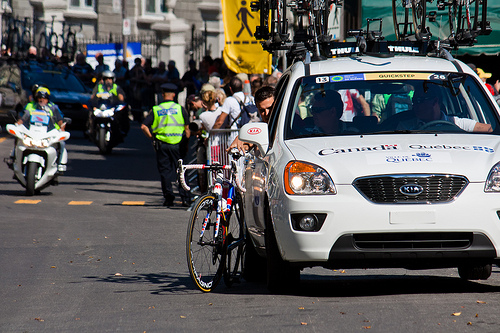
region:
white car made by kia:
[222, 50, 499, 287]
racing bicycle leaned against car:
[161, 147, 269, 298]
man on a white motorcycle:
[2, 83, 75, 208]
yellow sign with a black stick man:
[216, 0, 284, 93]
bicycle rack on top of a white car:
[245, 2, 499, 72]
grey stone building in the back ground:
[2, 0, 238, 70]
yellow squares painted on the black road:
[7, 191, 150, 219]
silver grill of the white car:
[350, 159, 475, 212]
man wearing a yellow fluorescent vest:
[136, 74, 199, 214]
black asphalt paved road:
[4, 139, 498, 331]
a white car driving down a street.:
[226, 55, 498, 292]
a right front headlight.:
[277, 153, 346, 232]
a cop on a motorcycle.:
[3, 81, 100, 218]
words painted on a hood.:
[316, 142, 496, 172]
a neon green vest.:
[141, 79, 198, 196]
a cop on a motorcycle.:
[76, 60, 132, 170]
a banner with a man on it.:
[204, 1, 288, 96]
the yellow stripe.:
[114, 191, 150, 217]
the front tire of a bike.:
[142, 177, 246, 312]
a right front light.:
[277, 208, 339, 258]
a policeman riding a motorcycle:
[2, 79, 81, 201]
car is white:
[219, 37, 498, 292]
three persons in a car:
[248, 83, 496, 135]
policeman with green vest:
[137, 79, 199, 209]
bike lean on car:
[161, 150, 253, 298]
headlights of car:
[281, 159, 498, 197]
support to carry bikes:
[251, 3, 496, 62]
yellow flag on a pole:
[214, 0, 280, 76]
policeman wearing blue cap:
[136, 74, 200, 207]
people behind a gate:
[188, 68, 257, 133]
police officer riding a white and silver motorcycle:
[3, 85, 70, 194]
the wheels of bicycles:
[245, 0, 493, 45]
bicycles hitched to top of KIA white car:
[248, 0, 497, 65]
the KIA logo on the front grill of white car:
[397, 181, 423, 195]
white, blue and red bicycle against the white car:
[174, 156, 244, 293]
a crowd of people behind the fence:
[184, 66, 254, 155]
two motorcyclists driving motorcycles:
[3, 69, 127, 196]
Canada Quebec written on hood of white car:
[318, 143, 470, 157]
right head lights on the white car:
[281, 159, 336, 195]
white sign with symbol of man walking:
[221, 0, 272, 71]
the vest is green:
[151, 102, 188, 142]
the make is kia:
[250, 63, 495, 265]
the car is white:
[236, 63, 498, 270]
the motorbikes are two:
[19, 79, 141, 182]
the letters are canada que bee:
[304, 130, 483, 162]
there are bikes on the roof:
[282, 15, 476, 47]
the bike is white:
[8, 128, 80, 188]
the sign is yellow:
[224, 13, 276, 73]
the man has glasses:
[406, 84, 480, 141]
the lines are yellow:
[57, 193, 146, 215]